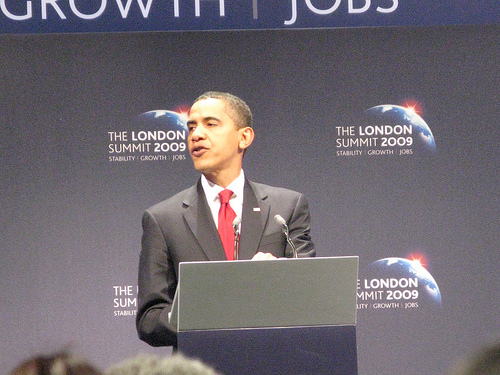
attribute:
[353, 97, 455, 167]
earth — picture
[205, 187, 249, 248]
tie — red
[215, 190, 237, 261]
tie — red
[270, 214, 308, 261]
microphone — podium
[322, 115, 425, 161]
logo — London Summit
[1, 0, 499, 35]
banner — larger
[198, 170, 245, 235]
shirt — white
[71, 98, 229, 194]
logo — for the london summit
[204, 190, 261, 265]
tie — red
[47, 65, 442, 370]
wall — blue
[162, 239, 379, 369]
podium — grey and blue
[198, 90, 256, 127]
hair — dark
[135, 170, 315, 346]
jacket — black, man's